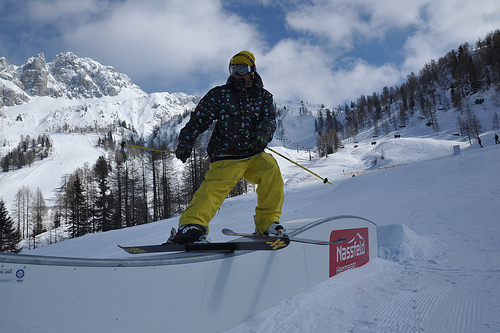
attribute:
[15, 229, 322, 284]
railing — silver, metal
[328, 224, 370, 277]
sign — red, snow-covered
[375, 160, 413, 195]
ground — winter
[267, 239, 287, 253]
design — yellow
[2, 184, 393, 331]
rail — stunt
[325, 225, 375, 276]
logo — red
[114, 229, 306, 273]
ski — black, metal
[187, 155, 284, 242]
pants — yellow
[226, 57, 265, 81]
goggles — for safety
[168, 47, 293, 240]
skier — extreme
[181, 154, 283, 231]
pants — bright yellow, snow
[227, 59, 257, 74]
goggles — reflective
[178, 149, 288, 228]
pants — yellow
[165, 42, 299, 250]
skier — extreme